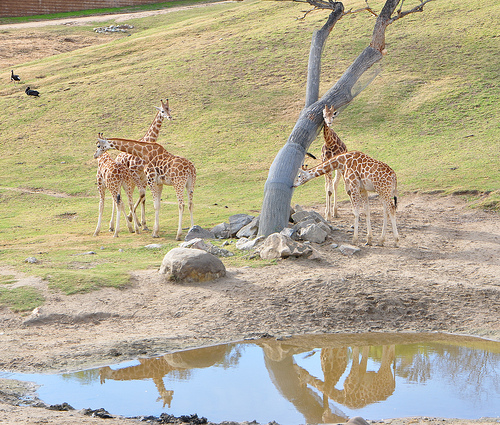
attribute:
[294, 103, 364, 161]
giraffes — walking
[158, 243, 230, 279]
rock — gray, large